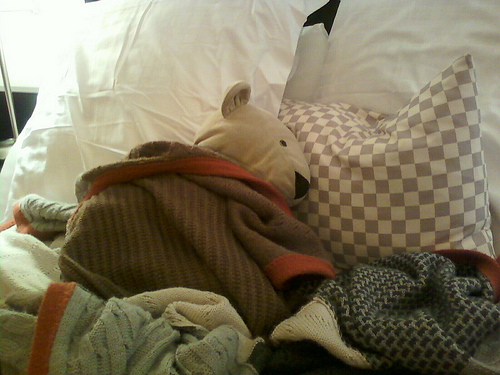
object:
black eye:
[278, 140, 288, 147]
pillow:
[272, 52, 499, 269]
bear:
[192, 78, 310, 206]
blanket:
[0, 189, 272, 375]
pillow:
[0, 0, 329, 231]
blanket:
[266, 247, 500, 375]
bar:
[0, 39, 19, 145]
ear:
[221, 80, 251, 119]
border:
[74, 155, 289, 218]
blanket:
[56, 140, 336, 337]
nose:
[293, 171, 311, 201]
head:
[193, 79, 313, 207]